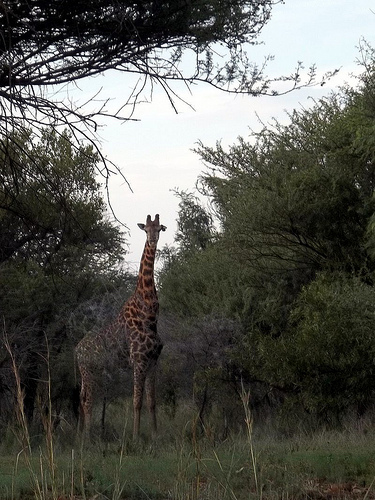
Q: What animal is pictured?
A: Giraffe.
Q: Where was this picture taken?
A: In the wild.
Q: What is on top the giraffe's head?
A: Horns.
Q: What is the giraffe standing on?
A: Grass.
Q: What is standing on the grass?
A: Giraffe.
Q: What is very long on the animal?
A: Neck.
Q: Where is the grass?
A: On ground.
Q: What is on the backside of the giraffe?
A: Tail.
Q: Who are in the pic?
A: Animals.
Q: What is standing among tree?
A: Giraffe.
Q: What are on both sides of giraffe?
A: Trees.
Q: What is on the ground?
A: Grass.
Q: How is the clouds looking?
A: White.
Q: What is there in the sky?
A: Clouds.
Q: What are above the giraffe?
A: Trees.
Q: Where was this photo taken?
A: The continent of Africa.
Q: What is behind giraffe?
A: Trees.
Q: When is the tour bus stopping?
A: No bus.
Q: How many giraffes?
A: One.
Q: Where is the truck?
A: No truck.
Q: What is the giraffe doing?
A: Standing.